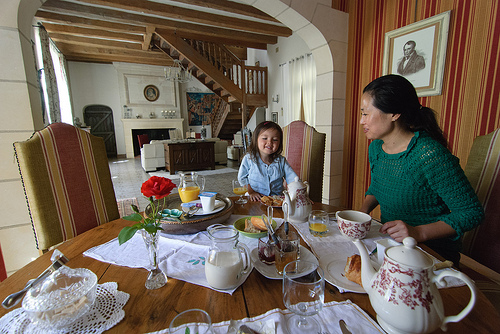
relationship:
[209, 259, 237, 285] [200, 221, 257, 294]
milk in pitcher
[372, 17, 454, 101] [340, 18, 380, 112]
portrait on wall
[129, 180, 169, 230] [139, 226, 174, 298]
flower in vase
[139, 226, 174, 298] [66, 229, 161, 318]
vase on table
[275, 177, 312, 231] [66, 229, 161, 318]
teapot on table